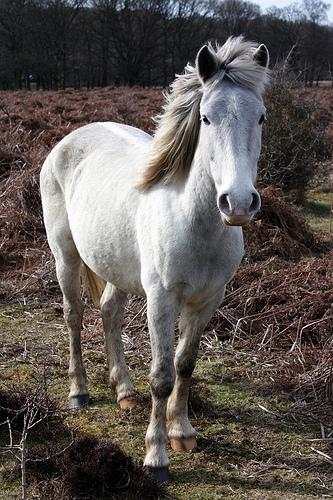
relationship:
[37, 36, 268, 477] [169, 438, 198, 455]
horse has a hoof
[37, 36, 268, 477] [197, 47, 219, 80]
horse has an ear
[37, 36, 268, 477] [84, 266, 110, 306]
horse has a tail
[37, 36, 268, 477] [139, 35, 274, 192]
horse has a mane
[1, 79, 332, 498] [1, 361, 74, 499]
grass has a stick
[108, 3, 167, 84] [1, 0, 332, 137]
tree in background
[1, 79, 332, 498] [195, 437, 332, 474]
grass has a shadow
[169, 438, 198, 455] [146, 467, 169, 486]
hoof that black